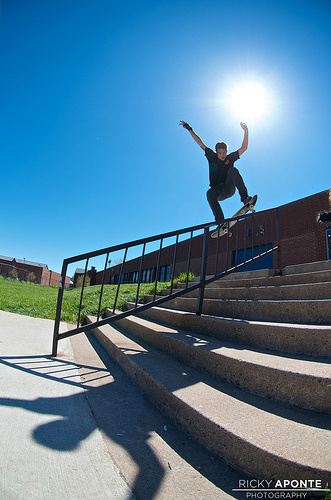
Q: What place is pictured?
A: It is a sidewalk.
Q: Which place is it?
A: It is a sidewalk.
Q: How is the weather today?
A: It is clear.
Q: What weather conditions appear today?
A: It is clear.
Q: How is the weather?
A: It is clear.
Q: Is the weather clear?
A: Yes, it is clear.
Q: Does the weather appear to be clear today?
A: Yes, it is clear.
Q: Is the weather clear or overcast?
A: It is clear.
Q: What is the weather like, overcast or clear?
A: It is clear.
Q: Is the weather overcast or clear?
A: It is clear.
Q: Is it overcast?
A: No, it is clear.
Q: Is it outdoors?
A: Yes, it is outdoors.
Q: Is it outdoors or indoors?
A: It is outdoors.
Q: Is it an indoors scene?
A: No, it is outdoors.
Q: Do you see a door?
A: Yes, there is a door.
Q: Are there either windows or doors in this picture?
A: Yes, there is a door.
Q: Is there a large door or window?
A: Yes, there is a large door.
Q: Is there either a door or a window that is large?
A: Yes, the door is large.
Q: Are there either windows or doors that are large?
A: Yes, the door is large.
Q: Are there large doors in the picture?
A: Yes, there is a large door.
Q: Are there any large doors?
A: Yes, there is a large door.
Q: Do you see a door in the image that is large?
A: Yes, there is a door that is large.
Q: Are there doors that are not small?
A: Yes, there is a large door.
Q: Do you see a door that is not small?
A: Yes, there is a large door.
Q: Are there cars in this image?
A: No, there are no cars.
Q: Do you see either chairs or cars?
A: No, there are no cars or chairs.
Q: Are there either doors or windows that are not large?
A: No, there is a door but it is large.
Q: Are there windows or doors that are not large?
A: No, there is a door but it is large.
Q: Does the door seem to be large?
A: Yes, the door is large.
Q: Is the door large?
A: Yes, the door is large.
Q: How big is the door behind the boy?
A: The door is large.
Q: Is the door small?
A: No, the door is large.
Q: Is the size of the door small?
A: No, the door is large.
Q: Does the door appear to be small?
A: No, the door is large.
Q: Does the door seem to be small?
A: No, the door is large.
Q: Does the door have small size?
A: No, the door is large.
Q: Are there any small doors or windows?
A: No, there is a door but it is large.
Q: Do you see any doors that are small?
A: No, there is a door but it is large.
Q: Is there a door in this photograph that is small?
A: No, there is a door but it is large.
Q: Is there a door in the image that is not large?
A: No, there is a door but it is large.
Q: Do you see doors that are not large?
A: No, there is a door but it is large.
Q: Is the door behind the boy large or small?
A: The door is large.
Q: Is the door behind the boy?
A: Yes, the door is behind the boy.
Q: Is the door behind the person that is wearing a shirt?
A: Yes, the door is behind the boy.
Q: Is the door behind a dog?
A: No, the door is behind the boy.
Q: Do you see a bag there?
A: No, there are no bags.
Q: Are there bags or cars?
A: No, there are no bags or cars.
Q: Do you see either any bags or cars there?
A: No, there are no bags or cars.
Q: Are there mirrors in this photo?
A: No, there are no mirrors.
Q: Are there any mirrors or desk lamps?
A: No, there are no mirrors or desk lamps.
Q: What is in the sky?
A: The sun is in the sky.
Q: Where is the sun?
A: The sun is in the sky.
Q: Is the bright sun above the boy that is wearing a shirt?
A: Yes, the sun is above the boy.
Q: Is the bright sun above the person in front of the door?
A: Yes, the sun is above the boy.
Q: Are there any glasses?
A: No, there are no glasses.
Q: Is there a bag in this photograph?
A: No, there are no bags.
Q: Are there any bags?
A: No, there are no bags.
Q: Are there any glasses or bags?
A: No, there are no bags or glasses.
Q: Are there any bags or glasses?
A: No, there are no bags or glasses.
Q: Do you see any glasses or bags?
A: No, there are no bags or glasses.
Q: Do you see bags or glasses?
A: No, there are no bags or glasses.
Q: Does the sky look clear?
A: Yes, the sky is clear.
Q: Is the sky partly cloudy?
A: No, the sky is clear.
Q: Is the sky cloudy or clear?
A: The sky is clear.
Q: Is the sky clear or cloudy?
A: The sky is clear.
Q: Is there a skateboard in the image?
A: Yes, there is a skateboard.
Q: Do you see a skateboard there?
A: Yes, there is a skateboard.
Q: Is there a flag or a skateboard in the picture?
A: Yes, there is a skateboard.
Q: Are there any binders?
A: No, there are no binders.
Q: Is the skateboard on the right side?
A: Yes, the skateboard is on the right of the image.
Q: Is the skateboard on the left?
A: No, the skateboard is on the right of the image.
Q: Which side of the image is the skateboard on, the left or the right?
A: The skateboard is on the right of the image.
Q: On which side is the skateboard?
A: The skateboard is on the right of the image.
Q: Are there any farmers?
A: No, there are no farmers.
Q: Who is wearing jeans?
A: The boy is wearing jeans.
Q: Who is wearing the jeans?
A: The boy is wearing jeans.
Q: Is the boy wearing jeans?
A: Yes, the boy is wearing jeans.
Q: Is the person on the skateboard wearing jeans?
A: Yes, the boy is wearing jeans.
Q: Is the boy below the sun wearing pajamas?
A: No, the boy is wearing jeans.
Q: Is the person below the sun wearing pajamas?
A: No, the boy is wearing jeans.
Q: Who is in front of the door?
A: The boy is in front of the door.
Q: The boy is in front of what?
A: The boy is in front of the door.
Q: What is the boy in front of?
A: The boy is in front of the door.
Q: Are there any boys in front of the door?
A: Yes, there is a boy in front of the door.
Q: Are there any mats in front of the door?
A: No, there is a boy in front of the door.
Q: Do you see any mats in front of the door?
A: No, there is a boy in front of the door.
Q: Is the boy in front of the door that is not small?
A: Yes, the boy is in front of the door.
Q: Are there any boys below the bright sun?
A: Yes, there is a boy below the sun.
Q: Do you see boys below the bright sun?
A: Yes, there is a boy below the sun.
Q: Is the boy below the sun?
A: Yes, the boy is below the sun.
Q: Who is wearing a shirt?
A: The boy is wearing a shirt.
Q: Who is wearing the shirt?
A: The boy is wearing a shirt.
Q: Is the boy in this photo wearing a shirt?
A: Yes, the boy is wearing a shirt.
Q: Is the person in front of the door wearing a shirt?
A: Yes, the boy is wearing a shirt.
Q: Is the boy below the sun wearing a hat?
A: No, the boy is wearing a shirt.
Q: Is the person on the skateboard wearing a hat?
A: No, the boy is wearing a shirt.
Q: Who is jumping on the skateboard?
A: The boy is jumping on the skateboard.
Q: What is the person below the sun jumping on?
A: The boy is jumping on the skateboard.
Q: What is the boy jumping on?
A: The boy is jumping on the skateboard.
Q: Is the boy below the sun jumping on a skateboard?
A: Yes, the boy is jumping on a skateboard.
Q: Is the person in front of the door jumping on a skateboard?
A: Yes, the boy is jumping on a skateboard.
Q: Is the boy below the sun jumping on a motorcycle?
A: No, the boy is jumping on a skateboard.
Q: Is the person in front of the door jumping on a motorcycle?
A: No, the boy is jumping on a skateboard.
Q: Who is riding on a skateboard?
A: The boy is riding on a skateboard.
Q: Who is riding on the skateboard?
A: The boy is riding on a skateboard.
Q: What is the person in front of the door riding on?
A: The boy is riding on a skateboard.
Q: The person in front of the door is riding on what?
A: The boy is riding on a skateboard.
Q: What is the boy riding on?
A: The boy is riding on a skateboard.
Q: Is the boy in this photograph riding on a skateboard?
A: Yes, the boy is riding on a skateboard.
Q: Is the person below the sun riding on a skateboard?
A: Yes, the boy is riding on a skateboard.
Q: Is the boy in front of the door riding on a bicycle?
A: No, the boy is riding on a skateboard.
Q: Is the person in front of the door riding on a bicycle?
A: No, the boy is riding on a skateboard.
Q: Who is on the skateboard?
A: The boy is on the skateboard.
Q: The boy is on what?
A: The boy is on the skateboard.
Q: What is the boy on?
A: The boy is on the skateboard.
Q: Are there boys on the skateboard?
A: Yes, there is a boy on the skateboard.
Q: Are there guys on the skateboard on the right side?
A: No, there is a boy on the skateboard.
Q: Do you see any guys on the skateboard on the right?
A: No, there is a boy on the skateboard.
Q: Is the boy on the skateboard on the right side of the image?
A: Yes, the boy is on the skateboard.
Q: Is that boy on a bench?
A: No, the boy is on the skateboard.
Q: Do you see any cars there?
A: No, there are no cars.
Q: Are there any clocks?
A: No, there are no clocks.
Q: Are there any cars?
A: No, there are no cars.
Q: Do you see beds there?
A: No, there are no beds.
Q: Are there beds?
A: No, there are no beds.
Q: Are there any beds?
A: No, there are no beds.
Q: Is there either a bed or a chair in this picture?
A: No, there are no beds or chairs.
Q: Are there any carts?
A: No, there are no carts.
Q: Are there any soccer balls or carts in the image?
A: No, there are no carts or soccer balls.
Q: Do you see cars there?
A: No, there are no cars.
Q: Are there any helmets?
A: No, there are no helmets.